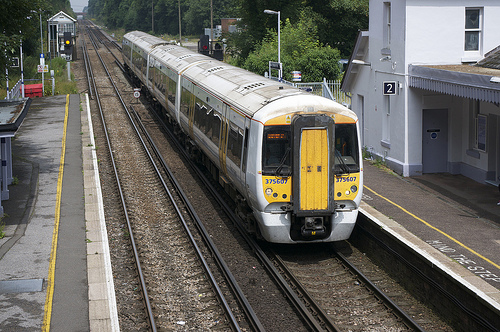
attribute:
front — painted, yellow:
[262, 109, 360, 209]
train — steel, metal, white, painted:
[121, 30, 364, 243]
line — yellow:
[43, 95, 70, 331]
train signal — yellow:
[61, 30, 74, 56]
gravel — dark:
[99, 45, 311, 331]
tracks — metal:
[81, 45, 424, 331]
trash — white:
[172, 317, 191, 327]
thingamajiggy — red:
[22, 82, 43, 100]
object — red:
[22, 81, 43, 98]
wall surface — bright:
[404, 6, 469, 64]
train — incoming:
[127, 39, 427, 289]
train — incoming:
[134, 46, 366, 256]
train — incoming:
[128, 21, 421, 294]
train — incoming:
[130, 21, 397, 259]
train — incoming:
[117, 24, 373, 262]